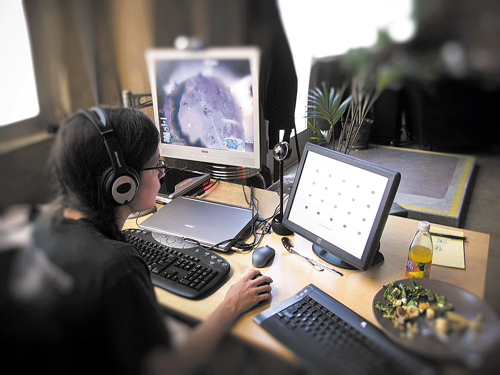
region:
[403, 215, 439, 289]
bottled beverage on desk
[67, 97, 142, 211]
headphones on brown hair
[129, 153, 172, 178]
glasses on girl's face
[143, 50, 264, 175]
desktop monitor that is on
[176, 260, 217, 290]
number pad on keyboard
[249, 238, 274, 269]
computer mouse on desk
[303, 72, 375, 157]
indoor plant on desk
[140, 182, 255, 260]
closed laptop on desk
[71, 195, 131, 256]
dark brown braided hair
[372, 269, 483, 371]
plate of food on desk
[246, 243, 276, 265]
A black computer mouse.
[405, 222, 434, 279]
A dark yellow drink in a plastic bottle.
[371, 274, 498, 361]
A dark colored plate with some food still on it.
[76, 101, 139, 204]
A pair of black and silver headphones.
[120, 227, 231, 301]
A rounded black and silver keyboard for a computer.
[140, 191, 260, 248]
A closed silver laptop.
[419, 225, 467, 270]
A yellow notepad.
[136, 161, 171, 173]
A pair of black framed glasses.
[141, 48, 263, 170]
A large silver flat screen computer monitor.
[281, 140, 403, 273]
A flat screen black laptop screen that is turned on.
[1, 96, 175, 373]
The woman is wearing headphones.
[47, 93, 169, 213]
The woman is wearing glasses.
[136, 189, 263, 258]
The laptop is gray.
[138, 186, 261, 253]
The laptop is closed.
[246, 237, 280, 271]
The mouse is wireless.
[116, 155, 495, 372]
The desk is wood.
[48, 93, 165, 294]
The woman has hair.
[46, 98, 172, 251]
The woman's hair is dark.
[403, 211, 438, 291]
The bottle is almost full.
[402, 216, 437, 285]
Bottle has yellow liquid in it.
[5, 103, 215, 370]
a young man sitting at a computer desk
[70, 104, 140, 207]
black earphones over the young man's head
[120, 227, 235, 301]
black computer keyboard on a desk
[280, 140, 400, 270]
a black computer monitor on a desk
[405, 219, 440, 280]
yellow drink in a bottle on a desk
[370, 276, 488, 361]
plate of food on a desk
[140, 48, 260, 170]
gray computer monitor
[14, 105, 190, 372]
young man wearing a black shirt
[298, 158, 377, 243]
row of icons displayed on a computer monitor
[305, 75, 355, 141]
a plant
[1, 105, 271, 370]
A woman wearing headphones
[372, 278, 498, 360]
A partially eaten salad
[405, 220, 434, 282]
A bottle of something yellow to drink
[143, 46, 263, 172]
A silver computer monitor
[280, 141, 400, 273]
A black computer monitor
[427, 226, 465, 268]
A yellow notepad on a desk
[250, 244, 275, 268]
An unused black computer mouse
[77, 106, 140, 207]
Black and silver headphones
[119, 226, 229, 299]
Most of a black and silver keyboard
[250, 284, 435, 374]
A black flat keyboard